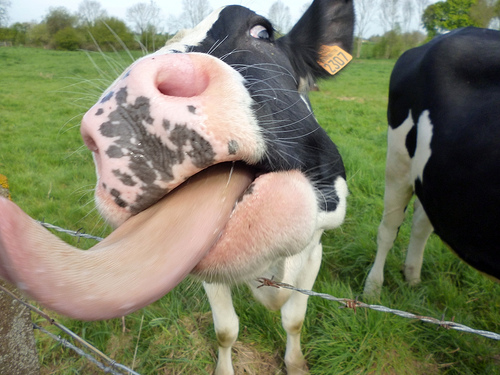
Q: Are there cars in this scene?
A: No, there are no cars.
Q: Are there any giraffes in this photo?
A: No, there are no giraffes.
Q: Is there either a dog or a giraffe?
A: No, there are no giraffes or dogs.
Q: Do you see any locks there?
A: No, there are no locks.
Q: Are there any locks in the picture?
A: No, there are no locks.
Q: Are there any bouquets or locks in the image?
A: No, there are no locks or bouquets.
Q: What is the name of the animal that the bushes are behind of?
A: The animal is a cow.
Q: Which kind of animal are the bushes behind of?
A: The bushes are behind the cow.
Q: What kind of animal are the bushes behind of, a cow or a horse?
A: The bushes are behind a cow.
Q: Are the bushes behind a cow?
A: Yes, the bushes are behind a cow.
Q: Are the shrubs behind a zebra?
A: No, the shrubs are behind a cow.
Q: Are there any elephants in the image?
A: No, there are no elephants.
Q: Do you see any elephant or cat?
A: No, there are no elephants or cats.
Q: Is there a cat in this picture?
A: No, there are no cats.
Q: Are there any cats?
A: No, there are no cats.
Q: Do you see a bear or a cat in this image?
A: No, there are no cats or bears.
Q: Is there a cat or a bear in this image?
A: No, there are no cats or bears.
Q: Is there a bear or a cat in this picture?
A: No, there are no cats or bears.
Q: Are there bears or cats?
A: No, there are no cats or bears.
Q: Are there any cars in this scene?
A: No, there are no cars.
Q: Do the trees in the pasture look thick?
A: Yes, the trees are thick.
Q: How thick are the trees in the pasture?
A: The trees are thick.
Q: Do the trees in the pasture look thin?
A: No, the trees are thick.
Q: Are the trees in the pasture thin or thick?
A: The trees are thick.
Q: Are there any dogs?
A: No, there are no dogs.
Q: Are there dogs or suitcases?
A: No, there are no dogs or suitcases.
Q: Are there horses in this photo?
A: No, there are no horses.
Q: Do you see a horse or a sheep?
A: No, there are no horses or sheep.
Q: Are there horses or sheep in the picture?
A: No, there are no horses or sheep.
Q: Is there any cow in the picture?
A: Yes, there is a cow.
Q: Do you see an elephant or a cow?
A: Yes, there is a cow.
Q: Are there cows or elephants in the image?
A: Yes, there is a cow.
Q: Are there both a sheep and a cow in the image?
A: No, there is a cow but no sheep.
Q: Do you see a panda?
A: No, there are no pandas.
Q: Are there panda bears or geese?
A: No, there are no panda bears or geese.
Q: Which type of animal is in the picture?
A: The animal is a cow.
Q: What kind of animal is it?
A: The animal is a cow.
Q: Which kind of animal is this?
A: That is a cow.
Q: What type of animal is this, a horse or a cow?
A: That is a cow.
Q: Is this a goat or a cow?
A: This is a cow.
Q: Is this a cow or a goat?
A: This is a cow.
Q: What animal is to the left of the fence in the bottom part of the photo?
A: The animal is a cow.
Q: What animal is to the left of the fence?
A: The animal is a cow.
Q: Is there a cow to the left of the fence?
A: Yes, there is a cow to the left of the fence.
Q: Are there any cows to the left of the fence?
A: Yes, there is a cow to the left of the fence.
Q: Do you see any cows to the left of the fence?
A: Yes, there is a cow to the left of the fence.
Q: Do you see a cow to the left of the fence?
A: Yes, there is a cow to the left of the fence.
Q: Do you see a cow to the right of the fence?
A: No, the cow is to the left of the fence.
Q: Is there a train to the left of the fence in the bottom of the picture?
A: No, there is a cow to the left of the fence.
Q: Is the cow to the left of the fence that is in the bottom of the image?
A: Yes, the cow is to the left of the fence.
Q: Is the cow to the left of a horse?
A: No, the cow is to the left of the fence.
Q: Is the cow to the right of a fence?
A: No, the cow is to the left of a fence.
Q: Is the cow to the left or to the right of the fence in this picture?
A: The cow is to the left of the fence.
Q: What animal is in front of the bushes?
A: The cow is in front of the bushes.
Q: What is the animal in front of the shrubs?
A: The animal is a cow.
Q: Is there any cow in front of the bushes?
A: Yes, there is a cow in front of the bushes.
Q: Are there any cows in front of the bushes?
A: Yes, there is a cow in front of the bushes.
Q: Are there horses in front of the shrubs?
A: No, there is a cow in front of the shrubs.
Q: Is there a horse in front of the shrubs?
A: No, there is a cow in front of the shrubs.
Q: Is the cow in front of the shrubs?
A: Yes, the cow is in front of the shrubs.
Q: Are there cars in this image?
A: No, there are no cars.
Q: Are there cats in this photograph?
A: No, there are no cats.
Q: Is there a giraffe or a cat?
A: No, there are no cats or giraffes.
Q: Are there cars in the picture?
A: No, there are no cars.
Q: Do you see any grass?
A: Yes, there is grass.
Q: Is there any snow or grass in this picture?
A: Yes, there is grass.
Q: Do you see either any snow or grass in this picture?
A: Yes, there is grass.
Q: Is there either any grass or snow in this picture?
A: Yes, there is grass.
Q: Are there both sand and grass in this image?
A: No, there is grass but no sand.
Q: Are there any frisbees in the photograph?
A: No, there are no frisbees.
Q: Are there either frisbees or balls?
A: No, there are no frisbees or balls.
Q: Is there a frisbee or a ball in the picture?
A: No, there are no frisbees or balls.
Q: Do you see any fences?
A: Yes, there is a fence.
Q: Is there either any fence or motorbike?
A: Yes, there is a fence.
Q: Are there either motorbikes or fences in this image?
A: Yes, there is a fence.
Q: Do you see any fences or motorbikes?
A: Yes, there is a fence.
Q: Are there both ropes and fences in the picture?
A: No, there is a fence but no ropes.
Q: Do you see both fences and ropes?
A: No, there is a fence but no ropes.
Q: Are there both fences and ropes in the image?
A: No, there is a fence but no ropes.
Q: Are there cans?
A: No, there are no cans.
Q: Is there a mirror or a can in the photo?
A: No, there are no cans or mirrors.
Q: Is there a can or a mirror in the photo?
A: No, there are no cans or mirrors.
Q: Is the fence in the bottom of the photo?
A: Yes, the fence is in the bottom of the image.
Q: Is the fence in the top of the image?
A: No, the fence is in the bottom of the image.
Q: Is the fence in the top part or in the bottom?
A: The fence is in the bottom of the image.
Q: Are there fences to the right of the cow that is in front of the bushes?
A: Yes, there is a fence to the right of the cow.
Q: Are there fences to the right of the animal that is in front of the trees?
A: Yes, there is a fence to the right of the cow.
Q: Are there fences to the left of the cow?
A: No, the fence is to the right of the cow.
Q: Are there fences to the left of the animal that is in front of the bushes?
A: No, the fence is to the right of the cow.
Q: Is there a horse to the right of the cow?
A: No, there is a fence to the right of the cow.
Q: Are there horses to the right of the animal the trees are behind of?
A: No, there is a fence to the right of the cow.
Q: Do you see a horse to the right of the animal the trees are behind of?
A: No, there is a fence to the right of the cow.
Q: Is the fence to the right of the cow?
A: Yes, the fence is to the right of the cow.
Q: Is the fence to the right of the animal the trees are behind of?
A: Yes, the fence is to the right of the cow.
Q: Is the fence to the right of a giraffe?
A: No, the fence is to the right of the cow.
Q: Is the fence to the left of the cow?
A: No, the fence is to the right of the cow.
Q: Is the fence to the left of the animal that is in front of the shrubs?
A: No, the fence is to the right of the cow.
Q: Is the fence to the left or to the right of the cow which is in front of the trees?
A: The fence is to the right of the cow.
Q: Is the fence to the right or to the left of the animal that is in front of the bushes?
A: The fence is to the right of the cow.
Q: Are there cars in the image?
A: No, there are no cars.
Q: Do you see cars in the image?
A: No, there are no cars.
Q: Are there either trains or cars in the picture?
A: No, there are no cars or trains.